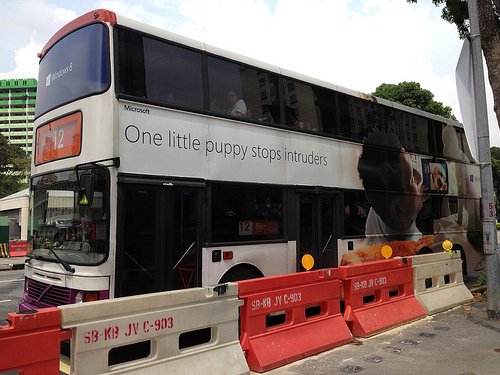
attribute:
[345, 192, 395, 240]
tinted window — large tinted bus 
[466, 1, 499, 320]
pole — grey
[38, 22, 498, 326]
bus — white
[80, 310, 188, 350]
lettering — red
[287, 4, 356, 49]
clouds — white 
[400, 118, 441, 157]
window — large tinted bus 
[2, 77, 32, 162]
building — green 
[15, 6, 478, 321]
bus — large , white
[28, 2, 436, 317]
bus — large tinted bus 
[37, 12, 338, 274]
bus — large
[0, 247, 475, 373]
barriers — white, red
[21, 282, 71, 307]
grill — purple 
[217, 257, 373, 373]
barricade — red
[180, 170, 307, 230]
bus — large tinted bus 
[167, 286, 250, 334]
barricade — white  